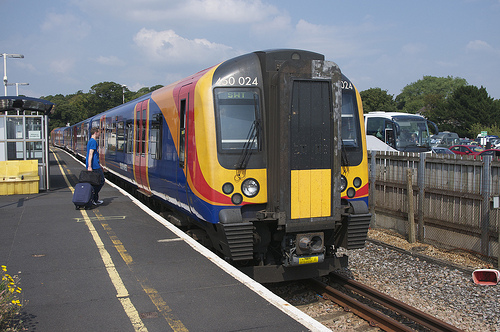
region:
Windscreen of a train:
[190, 81, 357, 150]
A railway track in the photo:
[308, 252, 471, 310]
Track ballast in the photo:
[365, 266, 478, 320]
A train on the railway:
[171, 70, 366, 235]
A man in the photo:
[75, 118, 109, 208]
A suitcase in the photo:
[70, 174, 107, 212]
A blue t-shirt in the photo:
[85, 137, 105, 172]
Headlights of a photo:
[227, 170, 362, 207]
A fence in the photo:
[401, 151, 486, 232]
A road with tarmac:
[35, 217, 183, 304]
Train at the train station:
[49, 49, 369, 294]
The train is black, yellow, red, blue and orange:
[53, 47, 378, 280]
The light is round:
[234, 172, 264, 200]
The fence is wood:
[367, 138, 492, 249]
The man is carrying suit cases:
[70, 120, 105, 205]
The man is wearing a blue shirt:
[75, 120, 105, 170]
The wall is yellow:
[0, 157, 40, 192]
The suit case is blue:
[70, 178, 96, 208]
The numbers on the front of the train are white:
[215, 73, 262, 87]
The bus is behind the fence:
[365, 104, 436, 158]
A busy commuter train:
[46, 61, 382, 293]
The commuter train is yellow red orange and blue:
[125, 51, 385, 210]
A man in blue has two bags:
[71, 116, 112, 217]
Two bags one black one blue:
[61, 160, 109, 207]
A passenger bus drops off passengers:
[366, 108, 443, 148]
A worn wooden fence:
[371, 151, 497, 249]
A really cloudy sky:
[5, 0, 495, 61]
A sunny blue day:
[0, 5, 495, 56]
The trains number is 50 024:
[215, 72, 265, 87]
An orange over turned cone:
[462, 261, 498, 303]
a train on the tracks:
[46, 52, 496, 325]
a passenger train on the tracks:
[85, 65, 471, 327]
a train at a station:
[28, 52, 489, 322]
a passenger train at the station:
[47, 59, 488, 285]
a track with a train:
[28, 63, 483, 310]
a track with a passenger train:
[71, 62, 403, 271]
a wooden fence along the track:
[274, 80, 497, 285]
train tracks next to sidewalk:
[227, 141, 475, 328]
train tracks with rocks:
[304, 205, 491, 316]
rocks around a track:
[204, 161, 498, 321]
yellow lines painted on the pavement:
[67, 219, 167, 330]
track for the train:
[334, 273, 406, 325]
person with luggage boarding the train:
[65, 128, 121, 216]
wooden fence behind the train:
[381, 145, 485, 245]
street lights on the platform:
[1, 48, 29, 94]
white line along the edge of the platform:
[159, 218, 213, 265]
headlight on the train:
[236, 174, 263, 197]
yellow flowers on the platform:
[4, 258, 29, 314]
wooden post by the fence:
[399, 160, 424, 240]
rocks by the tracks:
[399, 255, 465, 322]